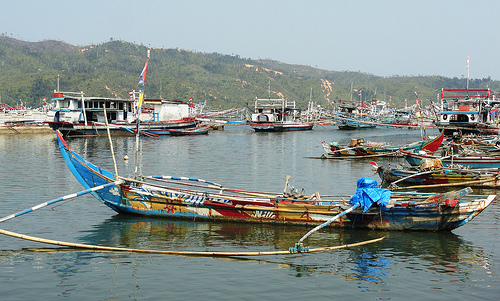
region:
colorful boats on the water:
[48, 92, 494, 253]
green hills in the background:
[2, 32, 498, 117]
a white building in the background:
[55, 92, 195, 126]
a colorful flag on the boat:
[137, 44, 150, 131]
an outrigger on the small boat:
[2, 172, 387, 265]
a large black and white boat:
[248, 96, 314, 134]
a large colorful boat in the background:
[434, 82, 499, 142]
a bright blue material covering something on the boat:
[353, 175, 393, 214]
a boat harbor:
[41, 71, 498, 258]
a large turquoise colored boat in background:
[332, 93, 379, 131]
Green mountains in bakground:
[1, 32, 498, 109]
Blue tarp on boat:
[355, 177, 391, 207]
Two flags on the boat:
[134, 46, 149, 121]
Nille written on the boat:
[247, 206, 282, 219]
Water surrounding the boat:
[203, 137, 358, 188]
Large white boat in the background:
[40, 82, 215, 129]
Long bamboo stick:
[5, 224, 387, 255]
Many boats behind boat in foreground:
[241, 89, 498, 163]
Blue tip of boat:
[47, 133, 126, 211]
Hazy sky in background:
[0, 0, 499, 75]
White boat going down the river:
[245, 89, 314, 136]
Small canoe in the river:
[34, 114, 493, 271]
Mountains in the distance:
[25, 29, 270, 113]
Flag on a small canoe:
[129, 34, 151, 176]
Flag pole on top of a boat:
[461, 54, 473, 90]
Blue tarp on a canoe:
[345, 170, 392, 210]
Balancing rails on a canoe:
[7, 179, 395, 276]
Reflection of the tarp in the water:
[346, 245, 396, 285]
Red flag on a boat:
[417, 124, 448, 158]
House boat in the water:
[48, 89, 213, 139]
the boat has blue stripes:
[43, 155, 294, 242]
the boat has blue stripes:
[73, 152, 208, 204]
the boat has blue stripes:
[0, 168, 235, 208]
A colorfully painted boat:
[52, 127, 493, 234]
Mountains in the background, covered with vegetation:
[1, 32, 498, 122]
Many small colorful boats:
[0, 87, 499, 255]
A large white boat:
[42, 89, 224, 136]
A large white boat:
[245, 98, 313, 131]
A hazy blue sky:
[0, 0, 499, 78]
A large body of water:
[1, 119, 498, 299]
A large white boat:
[437, 88, 498, 130]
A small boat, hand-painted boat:
[51, 127, 496, 232]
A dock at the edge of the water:
[0, 107, 54, 134]